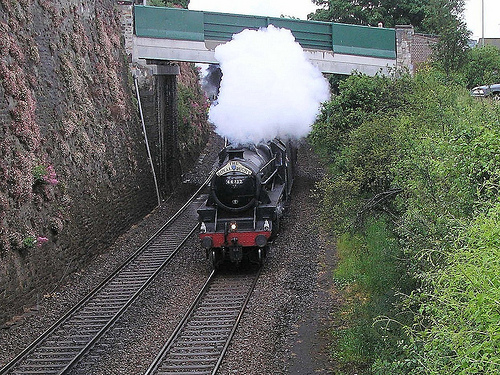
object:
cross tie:
[177, 330, 219, 359]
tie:
[4, 198, 207, 375]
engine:
[192, 140, 286, 271]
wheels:
[255, 247, 266, 268]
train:
[196, 141, 302, 274]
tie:
[151, 262, 259, 374]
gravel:
[46, 279, 274, 354]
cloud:
[205, 21, 333, 145]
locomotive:
[194, 135, 291, 268]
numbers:
[225, 179, 243, 185]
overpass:
[128, 5, 412, 78]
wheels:
[211, 248, 223, 268]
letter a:
[263, 219, 270, 230]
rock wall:
[8, 3, 212, 346]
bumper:
[195, 222, 271, 256]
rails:
[1, 164, 263, 373]